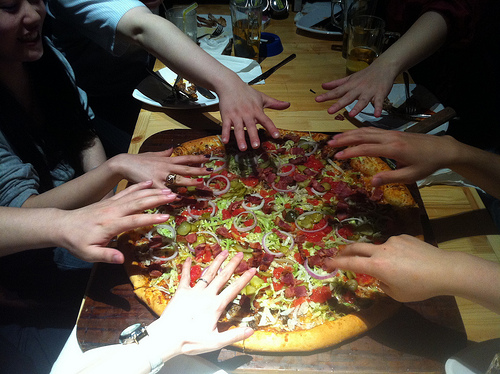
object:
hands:
[157, 249, 260, 354]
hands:
[68, 177, 178, 263]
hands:
[117, 145, 217, 201]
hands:
[213, 83, 292, 152]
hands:
[315, 63, 396, 119]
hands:
[327, 127, 454, 189]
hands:
[322, 231, 452, 303]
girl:
[2, 1, 215, 208]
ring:
[163, 172, 177, 186]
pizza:
[117, 127, 425, 354]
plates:
[131, 62, 244, 110]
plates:
[176, 11, 234, 41]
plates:
[295, 5, 362, 35]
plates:
[343, 82, 452, 141]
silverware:
[150, 65, 207, 100]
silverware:
[208, 24, 225, 43]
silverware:
[401, 70, 416, 115]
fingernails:
[202, 152, 212, 161]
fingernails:
[205, 167, 212, 173]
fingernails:
[194, 175, 202, 184]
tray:
[76, 127, 469, 373]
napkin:
[197, 34, 227, 55]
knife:
[249, 52, 299, 84]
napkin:
[207, 51, 265, 87]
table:
[47, 2, 500, 373]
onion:
[232, 210, 256, 232]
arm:
[0, 137, 122, 211]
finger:
[169, 154, 212, 164]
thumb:
[146, 150, 177, 159]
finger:
[161, 172, 204, 190]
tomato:
[222, 204, 231, 219]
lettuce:
[221, 237, 233, 250]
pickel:
[175, 218, 192, 236]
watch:
[116, 321, 166, 373]